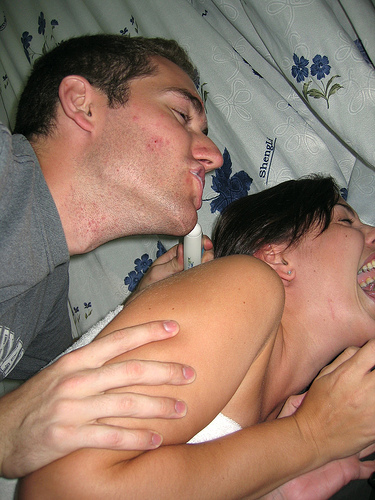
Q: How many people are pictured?
A: Two.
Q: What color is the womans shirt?
A: White.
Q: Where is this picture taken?
A: Bed.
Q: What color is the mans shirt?
A: Gray.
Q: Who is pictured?
A: Man and woman.